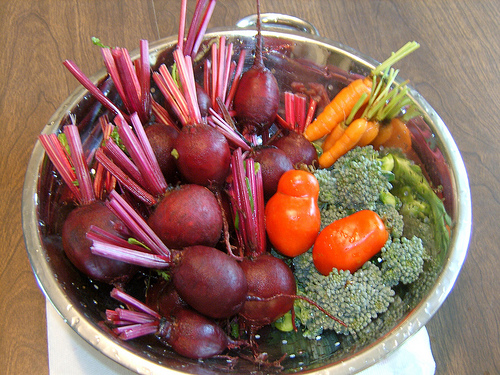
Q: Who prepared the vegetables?
A: Chef.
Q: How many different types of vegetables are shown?
A: Four.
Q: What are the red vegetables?
A: Beets.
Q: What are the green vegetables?
A: Broccoli.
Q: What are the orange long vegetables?
A: Carrots.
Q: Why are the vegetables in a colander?
A: To drain.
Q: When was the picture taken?
A: Daytime.